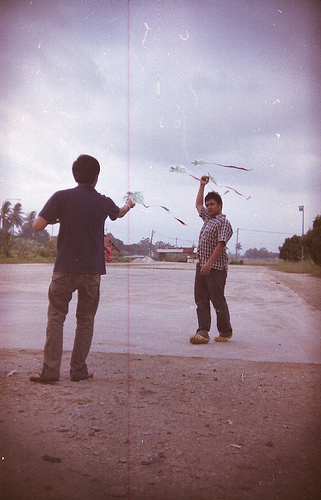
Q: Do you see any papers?
A: No, there are no papers.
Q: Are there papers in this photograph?
A: No, there are no papers.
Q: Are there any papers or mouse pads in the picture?
A: No, there are no papers or mouse pads.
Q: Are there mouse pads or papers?
A: No, there are no papers or mouse pads.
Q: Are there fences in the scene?
A: No, there are no fences.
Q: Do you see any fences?
A: No, there are no fences.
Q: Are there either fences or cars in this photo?
A: No, there are no fences or cars.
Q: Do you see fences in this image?
A: No, there are no fences.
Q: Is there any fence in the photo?
A: No, there are no fences.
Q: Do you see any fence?
A: No, there are no fences.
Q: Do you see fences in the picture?
A: No, there are no fences.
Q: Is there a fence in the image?
A: No, there are no fences.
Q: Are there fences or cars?
A: No, there are no fences or cars.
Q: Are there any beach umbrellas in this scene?
A: No, there are no beach umbrellas.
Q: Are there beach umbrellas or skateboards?
A: No, there are no beach umbrellas or skateboards.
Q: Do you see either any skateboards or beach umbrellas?
A: No, there are no beach umbrellas or skateboards.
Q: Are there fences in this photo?
A: No, there are no fences.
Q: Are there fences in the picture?
A: No, there are no fences.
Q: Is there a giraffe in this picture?
A: No, there are no giraffes.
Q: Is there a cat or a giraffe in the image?
A: No, there are no giraffes or cats.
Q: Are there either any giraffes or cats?
A: No, there are no giraffes or cats.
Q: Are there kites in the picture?
A: Yes, there is a kite.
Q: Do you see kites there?
A: Yes, there is a kite.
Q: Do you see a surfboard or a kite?
A: Yes, there is a kite.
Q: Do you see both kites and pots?
A: No, there is a kite but no pots.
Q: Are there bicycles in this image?
A: No, there are no bicycles.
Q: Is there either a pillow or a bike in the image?
A: No, there are no bikes or pillows.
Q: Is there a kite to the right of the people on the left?
A: Yes, there is a kite to the right of the people.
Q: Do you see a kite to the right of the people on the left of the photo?
A: Yes, there is a kite to the right of the people.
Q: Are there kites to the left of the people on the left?
A: No, the kite is to the right of the people.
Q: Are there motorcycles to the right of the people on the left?
A: No, there is a kite to the right of the people.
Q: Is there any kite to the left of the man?
A: Yes, there is a kite to the left of the man.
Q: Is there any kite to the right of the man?
A: No, the kite is to the left of the man.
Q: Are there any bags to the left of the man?
A: No, there is a kite to the left of the man.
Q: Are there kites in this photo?
A: Yes, there is a kite.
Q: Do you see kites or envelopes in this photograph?
A: Yes, there is a kite.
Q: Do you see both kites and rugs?
A: No, there is a kite but no rugs.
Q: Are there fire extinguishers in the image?
A: No, there are no fire extinguishers.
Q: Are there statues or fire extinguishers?
A: No, there are no fire extinguishers or statues.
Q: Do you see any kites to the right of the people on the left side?
A: Yes, there is a kite to the right of the people.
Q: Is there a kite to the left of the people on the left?
A: No, the kite is to the right of the people.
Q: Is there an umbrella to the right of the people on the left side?
A: No, there is a kite to the right of the people.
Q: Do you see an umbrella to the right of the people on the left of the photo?
A: No, there is a kite to the right of the people.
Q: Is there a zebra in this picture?
A: No, there are no zebras.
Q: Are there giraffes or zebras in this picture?
A: No, there are no zebras or giraffes.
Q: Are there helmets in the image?
A: No, there are no helmets.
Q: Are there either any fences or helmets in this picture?
A: No, there are no helmets or fences.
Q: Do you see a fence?
A: No, there are no fences.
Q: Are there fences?
A: No, there are no fences.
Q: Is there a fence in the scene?
A: No, there are no fences.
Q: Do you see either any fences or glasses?
A: No, there are no fences or glasses.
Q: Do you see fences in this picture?
A: No, there are no fences.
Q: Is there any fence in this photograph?
A: No, there are no fences.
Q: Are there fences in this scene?
A: No, there are no fences.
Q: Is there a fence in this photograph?
A: No, there are no fences.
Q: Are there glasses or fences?
A: No, there are no fences or glasses.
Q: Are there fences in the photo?
A: No, there are no fences.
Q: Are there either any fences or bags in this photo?
A: No, there are no fences or bags.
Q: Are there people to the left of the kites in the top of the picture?
A: Yes, there are people to the left of the kites.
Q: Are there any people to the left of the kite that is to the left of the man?
A: Yes, there are people to the left of the kite.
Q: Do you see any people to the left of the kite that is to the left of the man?
A: Yes, there are people to the left of the kite.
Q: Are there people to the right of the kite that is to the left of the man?
A: No, the people are to the left of the kite.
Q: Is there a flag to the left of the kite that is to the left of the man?
A: No, there are people to the left of the kite.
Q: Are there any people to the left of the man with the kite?
A: Yes, there are people to the left of the man.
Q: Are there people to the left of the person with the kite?
A: Yes, there are people to the left of the man.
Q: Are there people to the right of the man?
A: No, the people are to the left of the man.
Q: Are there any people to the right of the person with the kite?
A: No, the people are to the left of the man.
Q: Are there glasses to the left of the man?
A: No, there are people to the left of the man.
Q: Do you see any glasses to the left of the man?
A: No, there are people to the left of the man.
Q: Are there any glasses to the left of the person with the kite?
A: No, there are people to the left of the man.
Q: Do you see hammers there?
A: No, there are no hammers.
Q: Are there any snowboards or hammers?
A: No, there are no hammers or snowboards.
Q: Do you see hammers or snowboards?
A: No, there are no hammers or snowboards.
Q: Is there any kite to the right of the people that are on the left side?
A: Yes, there are kites to the right of the people.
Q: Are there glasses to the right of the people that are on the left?
A: No, there are kites to the right of the people.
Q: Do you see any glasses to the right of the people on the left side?
A: No, there are kites to the right of the people.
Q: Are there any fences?
A: No, there are no fences.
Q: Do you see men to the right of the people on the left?
A: Yes, there is a man to the right of the people.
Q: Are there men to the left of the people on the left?
A: No, the man is to the right of the people.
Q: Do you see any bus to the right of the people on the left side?
A: No, there is a man to the right of the people.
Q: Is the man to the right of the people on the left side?
A: Yes, the man is to the right of the people.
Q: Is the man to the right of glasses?
A: No, the man is to the right of the people.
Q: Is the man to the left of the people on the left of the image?
A: No, the man is to the right of the people.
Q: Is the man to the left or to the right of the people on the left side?
A: The man is to the right of the people.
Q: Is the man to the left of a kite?
A: No, the man is to the right of a kite.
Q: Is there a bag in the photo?
A: No, there are no bags.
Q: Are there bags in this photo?
A: No, there are no bags.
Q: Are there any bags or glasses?
A: No, there are no bags or glasses.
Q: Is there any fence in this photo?
A: No, there are no fences.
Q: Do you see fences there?
A: No, there are no fences.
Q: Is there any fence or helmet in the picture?
A: No, there are no fences or helmets.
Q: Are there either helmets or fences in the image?
A: No, there are no fences or helmets.